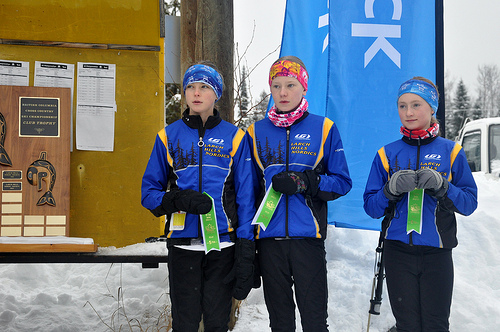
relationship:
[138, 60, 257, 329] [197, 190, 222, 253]
girl have just won an award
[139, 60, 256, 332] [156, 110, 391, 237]
girl are all jacket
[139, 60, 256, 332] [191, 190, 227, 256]
girl holding ribbon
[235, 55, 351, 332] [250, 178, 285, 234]
girl holding ribbon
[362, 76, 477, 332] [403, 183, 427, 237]
girl holding ribbon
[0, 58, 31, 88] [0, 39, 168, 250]
posting on wall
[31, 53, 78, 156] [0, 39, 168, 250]
posting on wall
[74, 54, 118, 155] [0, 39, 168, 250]
posting on wall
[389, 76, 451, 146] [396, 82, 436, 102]
girl wearing headband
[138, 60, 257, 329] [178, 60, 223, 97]
girl wearing headband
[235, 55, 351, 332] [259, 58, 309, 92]
girl wearing headband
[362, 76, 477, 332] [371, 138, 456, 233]
girl wearing jacket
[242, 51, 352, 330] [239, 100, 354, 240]
girl wearing jacket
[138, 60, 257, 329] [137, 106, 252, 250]
girl wearing jacket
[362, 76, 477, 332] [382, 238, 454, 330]
girl wearing pants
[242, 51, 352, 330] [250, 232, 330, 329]
girl wearing pants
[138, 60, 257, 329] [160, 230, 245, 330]
girl wearing pants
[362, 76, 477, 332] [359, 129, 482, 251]
girl wearing jacket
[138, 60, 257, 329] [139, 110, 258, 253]
girl wearing jacket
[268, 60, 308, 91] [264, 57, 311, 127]
bandanna on head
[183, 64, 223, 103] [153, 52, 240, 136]
bandana on head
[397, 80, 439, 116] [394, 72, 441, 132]
blue bandana on head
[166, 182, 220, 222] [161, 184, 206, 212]
mitten on girl's hand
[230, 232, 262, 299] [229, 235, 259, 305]
mitten on hand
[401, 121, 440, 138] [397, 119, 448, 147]
scarf around neck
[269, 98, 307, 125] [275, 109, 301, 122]
scarf around neck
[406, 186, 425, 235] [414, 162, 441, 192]
award in hand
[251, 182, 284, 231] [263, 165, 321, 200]
award in hand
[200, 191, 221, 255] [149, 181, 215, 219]
award in hand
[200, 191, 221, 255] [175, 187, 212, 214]
award in hand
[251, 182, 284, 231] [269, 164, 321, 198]
award in hand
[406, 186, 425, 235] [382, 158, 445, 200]
award in hand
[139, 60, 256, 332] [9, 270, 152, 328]
girl in snow